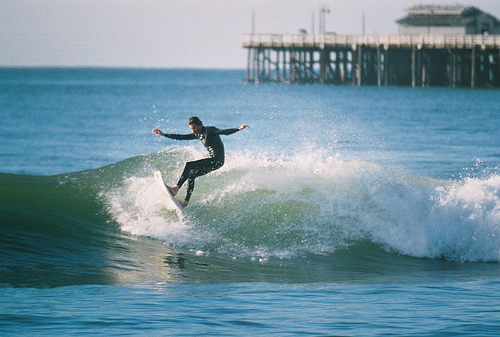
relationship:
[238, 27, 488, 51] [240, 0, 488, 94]
fence around deck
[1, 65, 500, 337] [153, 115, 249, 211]
water near surfer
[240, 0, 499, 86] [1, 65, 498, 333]
deck extending into water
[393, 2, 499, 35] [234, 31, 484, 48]
building on top of deck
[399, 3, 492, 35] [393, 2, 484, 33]
roof of building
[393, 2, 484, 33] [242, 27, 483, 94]
building on deck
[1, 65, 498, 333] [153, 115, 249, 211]
water near surfer